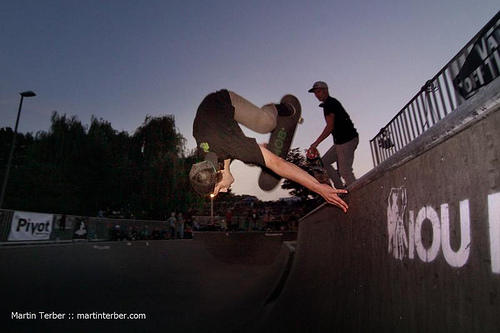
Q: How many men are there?
A: Two.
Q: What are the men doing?
A: Skateboarding.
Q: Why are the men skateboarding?
A: Recreation.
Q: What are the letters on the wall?
A: IOU.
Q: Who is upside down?
A: The closest skateboarder.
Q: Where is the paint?
A: Wall.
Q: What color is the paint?
A: White.